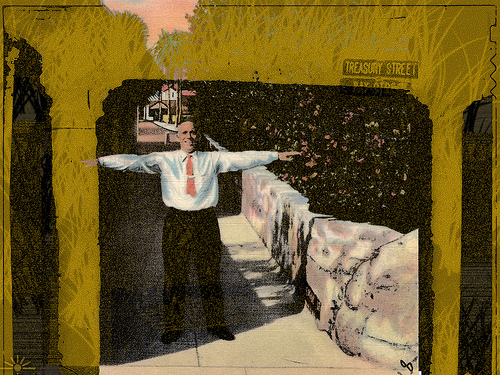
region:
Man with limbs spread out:
[78, 118, 314, 346]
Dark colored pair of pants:
[162, 200, 232, 330]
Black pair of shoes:
[158, 328, 236, 348]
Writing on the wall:
[340, 53, 421, 94]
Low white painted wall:
[236, 166, 396, 362]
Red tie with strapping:
[182, 151, 199, 199]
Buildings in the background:
[133, 76, 205, 148]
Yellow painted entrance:
[0, 0, 499, 374]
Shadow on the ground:
[91, 202, 284, 369]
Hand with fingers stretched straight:
[275, 148, 305, 165]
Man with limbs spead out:
[71, 118, 311, 348]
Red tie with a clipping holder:
[183, 153, 199, 199]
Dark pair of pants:
[161, 203, 230, 333]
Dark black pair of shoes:
[159, 325, 239, 350]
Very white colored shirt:
[95, 149, 281, 214]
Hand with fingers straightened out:
[276, 145, 304, 163]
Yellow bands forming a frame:
[0, 0, 498, 372]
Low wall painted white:
[207, 131, 426, 370]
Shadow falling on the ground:
[98, 218, 277, 372]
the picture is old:
[20, 20, 461, 350]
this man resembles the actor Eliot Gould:
[58, 92, 314, 354]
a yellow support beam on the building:
[28, 33, 134, 323]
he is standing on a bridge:
[123, 112, 268, 339]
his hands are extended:
[72, 111, 319, 187]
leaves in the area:
[238, 96, 410, 212]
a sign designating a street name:
[333, 37, 428, 107]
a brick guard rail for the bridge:
[246, 177, 409, 332]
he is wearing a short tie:
[170, 153, 206, 203]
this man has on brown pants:
[147, 202, 240, 327]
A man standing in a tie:
[102, 132, 280, 326]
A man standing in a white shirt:
[88, 119, 271, 354]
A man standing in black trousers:
[131, 111, 281, 343]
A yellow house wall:
[422, 84, 477, 366]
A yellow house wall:
[50, 154, 104, 371]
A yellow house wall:
[42, 6, 129, 91]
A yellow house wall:
[201, 13, 275, 85]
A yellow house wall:
[300, 4, 365, 89]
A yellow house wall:
[365, 5, 409, 87]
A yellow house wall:
[419, 2, 489, 97]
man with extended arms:
[103, 121, 300, 345]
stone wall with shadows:
[235, 165, 420, 365]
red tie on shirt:
[183, 154, 194, 196]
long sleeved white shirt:
[98, 150, 278, 212]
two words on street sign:
[341, 58, 423, 77]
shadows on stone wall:
[274, 210, 314, 287]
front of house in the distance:
[140, 85, 190, 122]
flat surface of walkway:
[123, 164, 324, 374]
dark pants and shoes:
[158, 208, 235, 341]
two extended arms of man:
[84, 150, 299, 174]